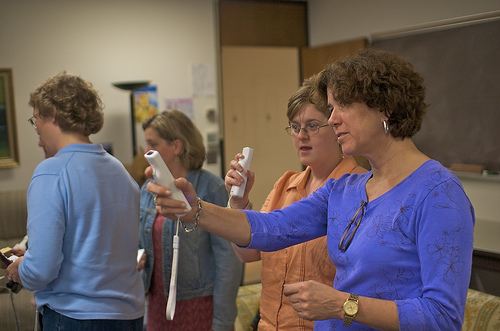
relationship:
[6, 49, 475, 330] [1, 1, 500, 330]
people in room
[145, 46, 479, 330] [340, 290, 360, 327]
woman wearing watch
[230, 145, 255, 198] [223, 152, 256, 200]
game control in hand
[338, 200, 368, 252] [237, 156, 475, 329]
glasses on shirt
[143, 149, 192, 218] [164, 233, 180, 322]
game control with handle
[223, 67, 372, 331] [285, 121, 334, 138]
woman wearing glasses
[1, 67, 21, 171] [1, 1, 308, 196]
picture on wall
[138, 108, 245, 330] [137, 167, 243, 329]
woman wearing jacket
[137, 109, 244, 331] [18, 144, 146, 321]
woman wearing shirt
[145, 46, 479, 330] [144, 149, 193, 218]
woman holding game control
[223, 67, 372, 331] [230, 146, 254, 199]
woman holding game control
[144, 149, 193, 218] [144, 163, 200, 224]
game control in hand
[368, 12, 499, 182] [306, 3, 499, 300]
blackboard on wall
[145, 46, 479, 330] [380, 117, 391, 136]
woman wearing earring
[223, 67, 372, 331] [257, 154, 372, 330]
woman wearing shirt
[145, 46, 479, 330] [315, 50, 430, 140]
woman with hair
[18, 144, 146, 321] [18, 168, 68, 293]
shirt has long sleeve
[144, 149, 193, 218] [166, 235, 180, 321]
game control has handle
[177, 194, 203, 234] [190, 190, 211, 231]
bracelet on wrist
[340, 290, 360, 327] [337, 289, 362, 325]
watch on wrist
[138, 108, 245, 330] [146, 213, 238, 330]
woman wearing dress